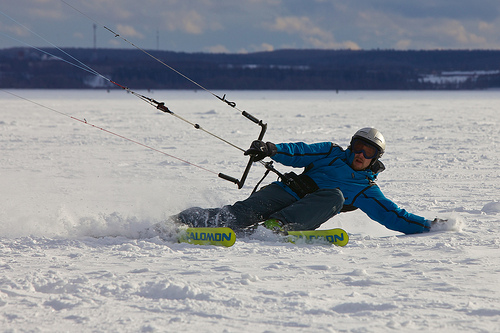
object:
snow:
[0, 88, 500, 333]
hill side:
[1, 85, 499, 331]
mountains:
[0, 46, 500, 91]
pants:
[177, 181, 345, 236]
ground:
[0, 241, 500, 333]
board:
[178, 227, 237, 248]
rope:
[0, 0, 244, 113]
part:
[156, 146, 182, 161]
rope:
[0, 88, 220, 176]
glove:
[243, 140, 277, 162]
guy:
[138, 127, 449, 249]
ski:
[278, 228, 350, 248]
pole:
[93, 23, 97, 52]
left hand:
[430, 217, 448, 231]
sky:
[0, 0, 500, 55]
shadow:
[353, 139, 370, 150]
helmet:
[350, 126, 386, 170]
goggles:
[351, 136, 385, 159]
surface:
[394, 238, 500, 319]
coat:
[177, 141, 432, 231]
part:
[359, 126, 369, 136]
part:
[262, 141, 271, 164]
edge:
[187, 227, 229, 230]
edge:
[208, 90, 233, 104]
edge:
[351, 137, 356, 148]